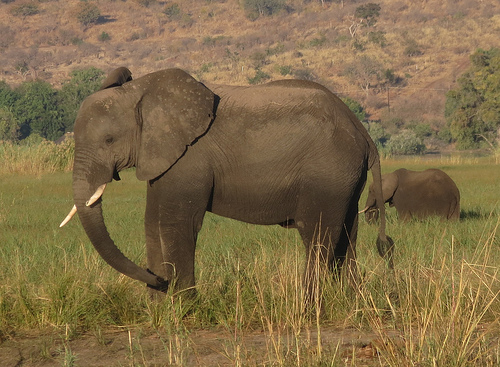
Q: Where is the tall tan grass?
A: In front of the green grass.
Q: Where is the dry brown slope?
A: In back of the elephant.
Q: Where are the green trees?
A: At the bottom of the slope.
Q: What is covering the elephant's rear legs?
A: Grass.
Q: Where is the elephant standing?
A: On the grass.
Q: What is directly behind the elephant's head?
A: The ear.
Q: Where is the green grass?
A: On the ground.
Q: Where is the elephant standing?
A: In a grassy field.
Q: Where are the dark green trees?
A: At the bottom of a hill.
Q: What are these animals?
A: Elephants.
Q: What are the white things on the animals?
A: Tusks.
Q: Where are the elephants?
A: In a field.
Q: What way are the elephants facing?
A: The left.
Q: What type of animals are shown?
A: Elephants.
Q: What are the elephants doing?
A: Standing.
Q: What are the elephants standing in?
A: Grass.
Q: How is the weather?
A: Clear.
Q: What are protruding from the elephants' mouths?
A: Horns.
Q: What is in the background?
A: Hills.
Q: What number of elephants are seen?
A: Two.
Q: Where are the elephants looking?
A: Down.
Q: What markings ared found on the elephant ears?
A: Spots.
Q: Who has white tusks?
A: The elephants.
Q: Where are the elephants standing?
A: On the grass.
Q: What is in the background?
A: Trees.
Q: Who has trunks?
A: Elephants.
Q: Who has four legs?
A: One elephant.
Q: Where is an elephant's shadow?
A: On the grass.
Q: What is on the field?
A: Elephants.